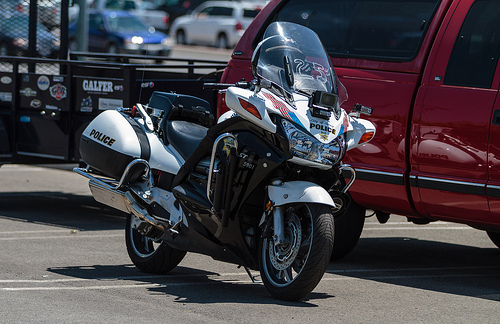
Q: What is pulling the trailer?
A: A red SUV.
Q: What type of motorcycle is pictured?
A: A police motorcycle.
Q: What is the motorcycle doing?
A: It is parked.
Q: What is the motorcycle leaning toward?
A: The red SUV.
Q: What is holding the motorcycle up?
A: A kickstand.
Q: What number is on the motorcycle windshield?
A: 25.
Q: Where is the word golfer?
A: On the black trailer.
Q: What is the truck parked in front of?
A: Subway stairs.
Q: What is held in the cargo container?
A: Supplies.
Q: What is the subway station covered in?
A: Stickers.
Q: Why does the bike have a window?
A: To shield wind.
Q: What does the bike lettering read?
A: Police.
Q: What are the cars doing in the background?
A: Driving.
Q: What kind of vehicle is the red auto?
A: Truck.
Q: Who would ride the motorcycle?
A: Policeman.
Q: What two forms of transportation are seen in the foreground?
A: Truck and motorcycle.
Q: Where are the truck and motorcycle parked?
A: Parking lot.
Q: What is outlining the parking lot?
A: White stripes.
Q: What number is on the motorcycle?
A: 25.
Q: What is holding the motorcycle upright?
A: A kickstand.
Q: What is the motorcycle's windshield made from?
A: Plexiglass.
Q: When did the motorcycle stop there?
A: A few minutes ago.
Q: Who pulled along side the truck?
A: Police.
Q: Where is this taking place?
A: A parking lot.